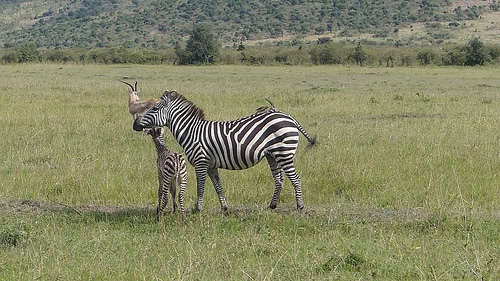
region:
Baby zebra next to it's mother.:
[135, 123, 197, 213]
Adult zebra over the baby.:
[126, 96, 326, 217]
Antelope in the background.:
[112, 73, 154, 117]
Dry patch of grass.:
[23, 187, 478, 240]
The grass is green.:
[23, 111, 111, 199]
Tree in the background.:
[168, 22, 223, 65]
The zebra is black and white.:
[188, 121, 288, 163]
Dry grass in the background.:
[403, 0, 498, 50]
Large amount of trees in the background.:
[51, 0, 301, 45]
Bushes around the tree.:
[11, 38, 176, 73]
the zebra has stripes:
[161, 93, 383, 260]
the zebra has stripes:
[86, 54, 345, 209]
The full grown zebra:
[129, 82, 318, 218]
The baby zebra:
[141, 123, 189, 221]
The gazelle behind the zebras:
[117, 76, 163, 121]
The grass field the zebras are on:
[1, 61, 498, 279]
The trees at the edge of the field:
[0, 18, 491, 67]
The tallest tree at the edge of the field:
[169, 20, 224, 63]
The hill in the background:
[0, 0, 498, 44]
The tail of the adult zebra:
[290, 118, 324, 158]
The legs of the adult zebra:
[186, 148, 308, 217]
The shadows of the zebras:
[57, 198, 251, 230]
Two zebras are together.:
[115, 67, 350, 234]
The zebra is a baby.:
[118, 117, 200, 227]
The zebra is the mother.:
[125, 82, 341, 222]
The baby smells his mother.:
[132, 115, 188, 229]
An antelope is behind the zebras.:
[106, 60, 186, 124]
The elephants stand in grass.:
[1, 74, 498, 279]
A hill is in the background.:
[0, 0, 497, 67]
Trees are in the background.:
[159, 9, 492, 74]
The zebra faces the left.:
[113, 80, 342, 220]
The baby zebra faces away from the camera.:
[135, 117, 196, 234]